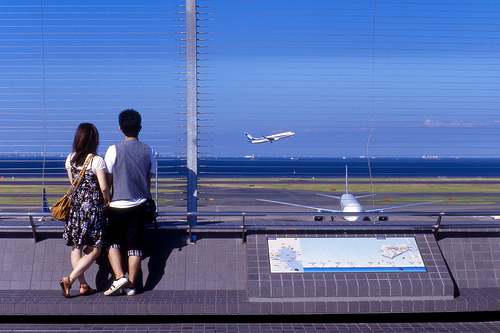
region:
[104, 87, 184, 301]
a man wearing a jacket around his waist.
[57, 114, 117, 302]
a woman in a flower print dress.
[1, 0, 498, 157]
a crystal blue sky.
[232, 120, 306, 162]
a jetliner flying into the blue sky.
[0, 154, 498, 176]
a blue water line.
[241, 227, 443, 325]
a section of a brick wall.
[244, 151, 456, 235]
a jetliner on a tarmac.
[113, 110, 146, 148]
a guy with black hair.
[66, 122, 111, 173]
a woman with long hair.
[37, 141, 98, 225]
a brown bag over a woman's shoulder.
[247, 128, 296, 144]
airplane flying in sky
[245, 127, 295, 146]
plane taking off from airport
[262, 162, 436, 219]
plane sitting on runway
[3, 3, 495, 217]
metal wire barrier fence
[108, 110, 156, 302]
man standing by fence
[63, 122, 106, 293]
girl wearing floral dress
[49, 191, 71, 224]
brown leather hobo bag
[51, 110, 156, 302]
couple watching airplanes take off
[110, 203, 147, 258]
black and grey shorts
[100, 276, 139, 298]
black and white sneakers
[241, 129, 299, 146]
An airplane taking off.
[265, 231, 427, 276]
A map inside a console.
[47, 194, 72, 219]
A brown, leather purse.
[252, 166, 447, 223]
A plane at rest on the tarmac.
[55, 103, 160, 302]
A couple stares out onto the airfield.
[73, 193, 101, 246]
A floral print dress.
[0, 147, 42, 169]
A city in the distance.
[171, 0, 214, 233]
A support column for the window.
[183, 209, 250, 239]
A guard rail leaning against the window.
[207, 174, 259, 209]
An paved airfield, surrounded by grass.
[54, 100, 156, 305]
Couple watches airplanes taking off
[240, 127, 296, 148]
Airplane is in the air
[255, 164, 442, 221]
airplane is being taxi to terminal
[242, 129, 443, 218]
two airplanes are shown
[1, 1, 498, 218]
Fence between people and airplanes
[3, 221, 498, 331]
People stand on brick walkway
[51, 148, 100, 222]
The woman is wearing a purse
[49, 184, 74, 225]
The purse is brown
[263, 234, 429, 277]
Infographic on brick altar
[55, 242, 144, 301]
People have one foot raised each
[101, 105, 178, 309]
young man watching plane take off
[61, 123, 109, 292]
young woman watching plane take off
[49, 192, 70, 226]
brown purse worn by young woman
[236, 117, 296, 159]
plane taking off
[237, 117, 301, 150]
plane taking off at airport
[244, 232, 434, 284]
map containing description of airport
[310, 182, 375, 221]
parked white plane at airport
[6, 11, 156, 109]
blue sky without clouds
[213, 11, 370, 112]
blue sky without clouds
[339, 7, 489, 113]
blue sky without clouds